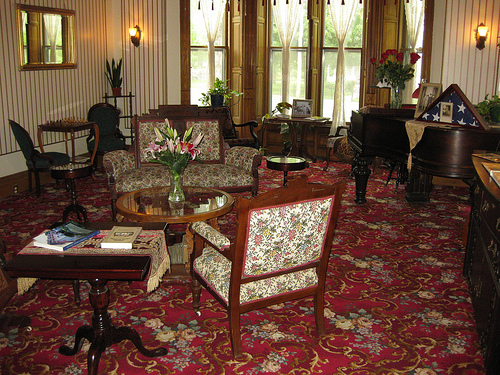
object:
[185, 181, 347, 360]
chair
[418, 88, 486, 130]
flag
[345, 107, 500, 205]
piano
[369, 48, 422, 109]
roses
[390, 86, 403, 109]
vase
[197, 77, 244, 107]
plant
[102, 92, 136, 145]
shelf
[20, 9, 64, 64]
mirror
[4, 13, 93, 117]
wall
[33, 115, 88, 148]
sidebar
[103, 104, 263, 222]
couch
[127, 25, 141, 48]
light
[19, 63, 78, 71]
frame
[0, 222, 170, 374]
wood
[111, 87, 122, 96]
pot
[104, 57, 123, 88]
greenery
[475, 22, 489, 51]
lights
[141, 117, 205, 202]
flowers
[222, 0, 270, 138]
curtains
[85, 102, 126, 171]
seat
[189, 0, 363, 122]
window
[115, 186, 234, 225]
board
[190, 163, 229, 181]
fabric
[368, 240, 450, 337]
floor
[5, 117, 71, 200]
seats